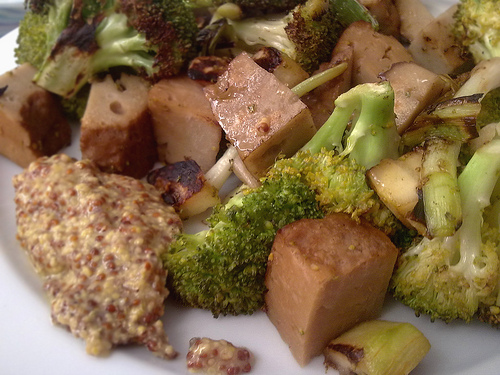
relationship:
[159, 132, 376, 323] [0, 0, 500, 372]
broccoli on dish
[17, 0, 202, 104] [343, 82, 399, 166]
broccoli has broccoli stem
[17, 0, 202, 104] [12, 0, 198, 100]
broccoli has top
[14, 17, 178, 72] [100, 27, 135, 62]
broccoli color green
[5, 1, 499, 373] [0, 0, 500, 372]
stirfry on dish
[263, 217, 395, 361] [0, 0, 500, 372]
meat piece on dish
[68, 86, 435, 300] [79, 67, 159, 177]
dish full of meat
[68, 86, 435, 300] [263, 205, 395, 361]
dish full of meat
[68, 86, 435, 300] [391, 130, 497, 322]
dish full of vegetables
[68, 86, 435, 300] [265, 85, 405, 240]
dish full of vegetables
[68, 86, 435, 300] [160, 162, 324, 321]
dish full of vegetables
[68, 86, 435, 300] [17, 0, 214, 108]
dish full of vegetables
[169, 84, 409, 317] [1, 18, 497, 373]
broccoli touching gravy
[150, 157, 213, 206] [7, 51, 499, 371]
burnt veggie touching a gravy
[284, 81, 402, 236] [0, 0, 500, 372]
broccoli on dish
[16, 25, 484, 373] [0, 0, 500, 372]
food on dish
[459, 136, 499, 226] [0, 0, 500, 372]
broccoli stem sticking up on dish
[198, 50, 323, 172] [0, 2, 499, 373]
meat on food